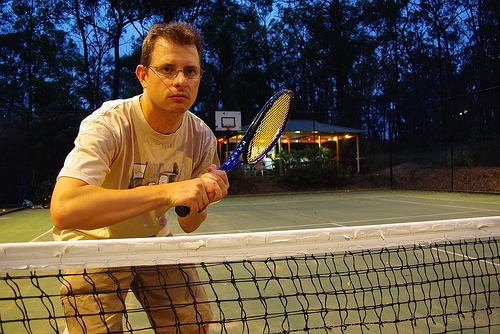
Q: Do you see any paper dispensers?
A: No, there are no paper dispensers.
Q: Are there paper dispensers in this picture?
A: No, there are no paper dispensers.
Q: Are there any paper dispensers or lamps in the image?
A: No, there are no paper dispensers or lamps.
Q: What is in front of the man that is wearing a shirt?
A: The net is in front of the man.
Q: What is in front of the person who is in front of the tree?
A: The net is in front of the man.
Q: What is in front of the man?
A: The net is in front of the man.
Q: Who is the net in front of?
A: The net is in front of the man.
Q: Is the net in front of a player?
A: No, the net is in front of the man.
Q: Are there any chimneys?
A: No, there are no chimneys.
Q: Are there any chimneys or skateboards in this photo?
A: No, there are no chimneys or skateboards.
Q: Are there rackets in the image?
A: Yes, there is a racket.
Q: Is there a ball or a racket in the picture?
A: Yes, there is a racket.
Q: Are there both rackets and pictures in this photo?
A: No, there is a racket but no pictures.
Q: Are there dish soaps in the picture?
A: No, there are no dish soaps.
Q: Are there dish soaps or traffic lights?
A: No, there are no dish soaps or traffic lights.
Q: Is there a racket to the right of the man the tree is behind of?
A: Yes, there is a racket to the right of the man.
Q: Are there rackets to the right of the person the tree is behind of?
A: Yes, there is a racket to the right of the man.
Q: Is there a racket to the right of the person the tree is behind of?
A: Yes, there is a racket to the right of the man.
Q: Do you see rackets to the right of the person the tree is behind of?
A: Yes, there is a racket to the right of the man.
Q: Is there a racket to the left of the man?
A: No, the racket is to the right of the man.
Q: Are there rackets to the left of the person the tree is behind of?
A: No, the racket is to the right of the man.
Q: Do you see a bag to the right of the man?
A: No, there is a racket to the right of the man.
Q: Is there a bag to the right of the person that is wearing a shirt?
A: No, there is a racket to the right of the man.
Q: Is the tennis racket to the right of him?
A: Yes, the tennis racket is to the right of the man.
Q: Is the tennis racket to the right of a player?
A: No, the tennis racket is to the right of the man.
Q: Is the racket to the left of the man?
A: No, the racket is to the right of the man.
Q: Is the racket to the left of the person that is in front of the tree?
A: No, the racket is to the right of the man.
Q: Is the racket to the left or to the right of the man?
A: The racket is to the right of the man.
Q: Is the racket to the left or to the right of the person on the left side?
A: The racket is to the right of the man.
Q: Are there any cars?
A: No, there are no cars.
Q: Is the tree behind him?
A: Yes, the tree is behind the man.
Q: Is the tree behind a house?
A: No, the tree is behind the man.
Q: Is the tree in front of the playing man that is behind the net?
A: No, the tree is behind the man.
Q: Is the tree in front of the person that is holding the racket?
A: No, the tree is behind the man.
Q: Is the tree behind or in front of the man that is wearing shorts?
A: The tree is behind the man.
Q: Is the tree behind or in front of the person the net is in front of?
A: The tree is behind the man.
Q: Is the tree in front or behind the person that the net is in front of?
A: The tree is behind the man.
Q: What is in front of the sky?
A: The tree is in front of the sky.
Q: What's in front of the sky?
A: The tree is in front of the sky.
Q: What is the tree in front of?
A: The tree is in front of the sky.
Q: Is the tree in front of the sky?
A: Yes, the tree is in front of the sky.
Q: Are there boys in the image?
A: No, there are no boys.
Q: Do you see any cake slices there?
A: No, there are no cake slices.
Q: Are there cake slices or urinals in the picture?
A: No, there are no cake slices or urinals.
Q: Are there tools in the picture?
A: No, there are no tools.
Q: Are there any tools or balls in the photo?
A: No, there are no tools or balls.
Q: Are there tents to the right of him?
A: Yes, there is a tent to the right of the man.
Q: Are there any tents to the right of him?
A: Yes, there is a tent to the right of the man.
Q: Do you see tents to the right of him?
A: Yes, there is a tent to the right of the man.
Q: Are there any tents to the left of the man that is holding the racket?
A: No, the tent is to the right of the man.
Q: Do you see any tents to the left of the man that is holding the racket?
A: No, the tent is to the right of the man.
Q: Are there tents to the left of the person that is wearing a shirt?
A: No, the tent is to the right of the man.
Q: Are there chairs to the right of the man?
A: No, there is a tent to the right of the man.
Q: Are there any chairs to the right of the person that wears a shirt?
A: No, there is a tent to the right of the man.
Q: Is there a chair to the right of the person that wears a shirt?
A: No, there is a tent to the right of the man.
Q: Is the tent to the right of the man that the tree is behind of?
A: Yes, the tent is to the right of the man.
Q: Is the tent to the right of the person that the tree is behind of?
A: Yes, the tent is to the right of the man.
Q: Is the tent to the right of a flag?
A: No, the tent is to the right of the man.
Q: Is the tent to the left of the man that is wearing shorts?
A: No, the tent is to the right of the man.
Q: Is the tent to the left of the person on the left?
A: No, the tent is to the right of the man.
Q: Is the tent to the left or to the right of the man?
A: The tent is to the right of the man.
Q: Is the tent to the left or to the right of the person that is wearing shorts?
A: The tent is to the right of the man.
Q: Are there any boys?
A: No, there are no boys.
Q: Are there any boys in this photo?
A: No, there are no boys.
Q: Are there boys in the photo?
A: No, there are no boys.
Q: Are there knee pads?
A: No, there are no knee pads.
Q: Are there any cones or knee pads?
A: No, there are no knee pads or cones.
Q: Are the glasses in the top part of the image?
A: Yes, the glasses are in the top of the image.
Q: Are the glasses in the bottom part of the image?
A: No, the glasses are in the top of the image.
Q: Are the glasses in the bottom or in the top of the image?
A: The glasses are in the top of the image.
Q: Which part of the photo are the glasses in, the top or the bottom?
A: The glasses are in the top of the image.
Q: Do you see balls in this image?
A: No, there are no balls.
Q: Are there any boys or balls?
A: No, there are no balls or boys.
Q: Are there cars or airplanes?
A: No, there are no cars or airplanes.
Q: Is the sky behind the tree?
A: Yes, the sky is behind the tree.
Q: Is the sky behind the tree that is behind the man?
A: Yes, the sky is behind the tree.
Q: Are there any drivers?
A: No, there are no drivers.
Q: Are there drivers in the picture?
A: No, there are no drivers.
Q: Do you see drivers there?
A: No, there are no drivers.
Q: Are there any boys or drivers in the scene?
A: No, there are no drivers or boys.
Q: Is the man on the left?
A: Yes, the man is on the left of the image.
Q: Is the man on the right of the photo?
A: No, the man is on the left of the image.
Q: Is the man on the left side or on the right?
A: The man is on the left of the image.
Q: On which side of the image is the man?
A: The man is on the left of the image.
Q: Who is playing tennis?
A: The man is playing tennis.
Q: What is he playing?
A: The man is playing tennis.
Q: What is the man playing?
A: The man is playing tennis.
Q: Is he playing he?
A: Yes, the man is playing tennis.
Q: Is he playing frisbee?
A: No, the man is playing tennis.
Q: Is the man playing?
A: Yes, the man is playing.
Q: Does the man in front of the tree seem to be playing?
A: Yes, the man is playing.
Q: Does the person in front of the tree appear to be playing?
A: Yes, the man is playing.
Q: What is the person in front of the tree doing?
A: The man is playing.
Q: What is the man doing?
A: The man is playing.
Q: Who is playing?
A: The man is playing.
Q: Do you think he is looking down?
A: No, the man is playing.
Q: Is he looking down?
A: No, the man is playing.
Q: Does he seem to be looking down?
A: No, the man is playing.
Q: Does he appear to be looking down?
A: No, the man is playing.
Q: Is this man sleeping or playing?
A: The man is playing.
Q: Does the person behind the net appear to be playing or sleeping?
A: The man is playing.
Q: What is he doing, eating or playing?
A: The man is playing.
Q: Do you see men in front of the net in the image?
A: No, the man is behind the net.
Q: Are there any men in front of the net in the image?
A: No, the man is behind the net.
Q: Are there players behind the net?
A: No, there is a man behind the net.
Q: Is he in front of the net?
A: No, the man is behind the net.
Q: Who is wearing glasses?
A: The man is wearing glasses.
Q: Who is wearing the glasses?
A: The man is wearing glasses.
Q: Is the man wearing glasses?
A: Yes, the man is wearing glasses.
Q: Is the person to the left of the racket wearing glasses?
A: Yes, the man is wearing glasses.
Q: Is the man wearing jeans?
A: No, the man is wearing glasses.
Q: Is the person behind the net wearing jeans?
A: No, the man is wearing glasses.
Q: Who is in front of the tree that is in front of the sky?
A: The man is in front of the tree.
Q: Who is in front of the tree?
A: The man is in front of the tree.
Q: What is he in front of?
A: The man is in front of the tree.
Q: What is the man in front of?
A: The man is in front of the tree.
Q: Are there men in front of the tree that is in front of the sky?
A: Yes, there is a man in front of the tree.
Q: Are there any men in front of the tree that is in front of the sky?
A: Yes, there is a man in front of the tree.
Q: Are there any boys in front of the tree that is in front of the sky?
A: No, there is a man in front of the tree.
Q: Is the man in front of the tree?
A: Yes, the man is in front of the tree.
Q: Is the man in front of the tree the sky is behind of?
A: Yes, the man is in front of the tree.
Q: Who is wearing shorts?
A: The man is wearing shorts.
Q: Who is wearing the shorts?
A: The man is wearing shorts.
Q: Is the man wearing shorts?
A: Yes, the man is wearing shorts.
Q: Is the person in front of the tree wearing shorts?
A: Yes, the man is wearing shorts.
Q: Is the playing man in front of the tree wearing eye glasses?
A: No, the man is wearing shorts.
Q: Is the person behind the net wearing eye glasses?
A: No, the man is wearing shorts.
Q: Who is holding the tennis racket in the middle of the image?
A: The man is holding the tennis racket.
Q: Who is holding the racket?
A: The man is holding the tennis racket.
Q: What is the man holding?
A: The man is holding the racket.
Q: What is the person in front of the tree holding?
A: The man is holding the racket.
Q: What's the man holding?
A: The man is holding the racket.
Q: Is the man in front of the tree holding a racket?
A: Yes, the man is holding a racket.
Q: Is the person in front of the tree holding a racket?
A: Yes, the man is holding a racket.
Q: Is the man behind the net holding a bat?
A: No, the man is holding a racket.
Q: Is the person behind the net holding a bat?
A: No, the man is holding a racket.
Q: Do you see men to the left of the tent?
A: Yes, there is a man to the left of the tent.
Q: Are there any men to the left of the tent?
A: Yes, there is a man to the left of the tent.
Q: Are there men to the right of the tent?
A: No, the man is to the left of the tent.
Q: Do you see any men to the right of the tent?
A: No, the man is to the left of the tent.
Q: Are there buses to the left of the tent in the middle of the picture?
A: No, there is a man to the left of the tent.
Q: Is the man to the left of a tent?
A: Yes, the man is to the left of a tent.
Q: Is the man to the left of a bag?
A: No, the man is to the left of a tent.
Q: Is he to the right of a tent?
A: No, the man is to the left of a tent.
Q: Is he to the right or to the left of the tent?
A: The man is to the left of the tent.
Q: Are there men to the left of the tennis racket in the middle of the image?
A: Yes, there is a man to the left of the racket.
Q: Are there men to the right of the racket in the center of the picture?
A: No, the man is to the left of the racket.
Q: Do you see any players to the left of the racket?
A: No, there is a man to the left of the racket.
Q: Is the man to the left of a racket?
A: Yes, the man is to the left of a racket.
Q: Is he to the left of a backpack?
A: No, the man is to the left of a racket.